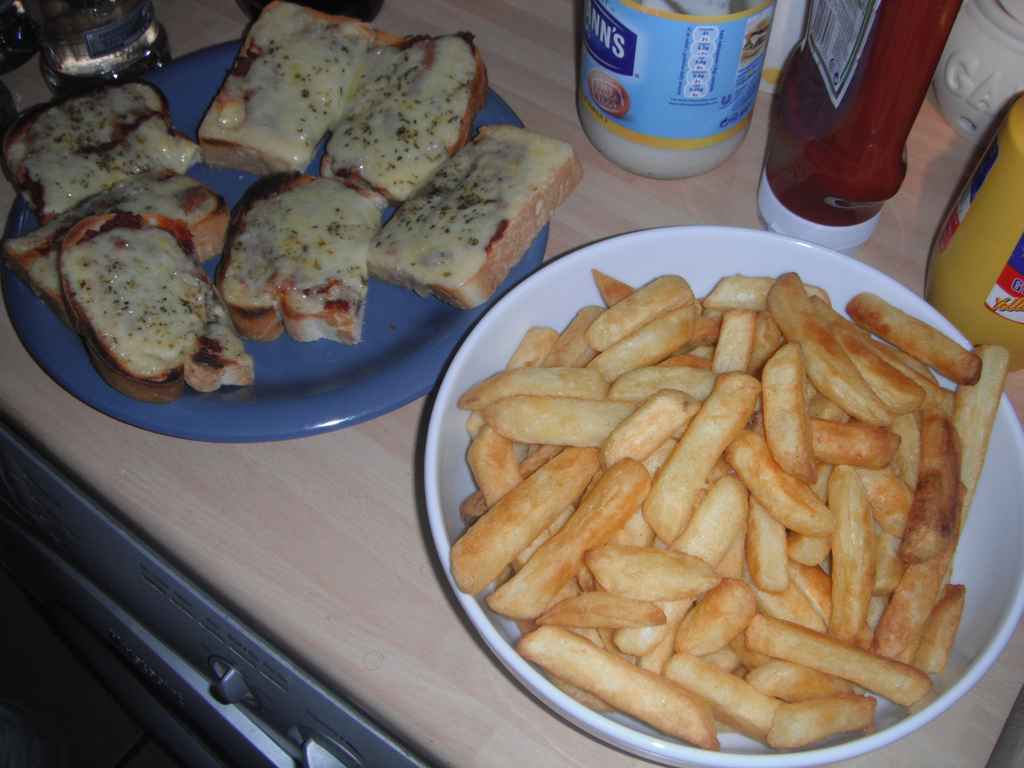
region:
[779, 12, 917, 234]
A bottle of ketchup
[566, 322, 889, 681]
A two to three servings of fries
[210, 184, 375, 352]
One piece of grilled cheese toast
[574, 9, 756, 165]
A large size of mayonnaise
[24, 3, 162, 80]
A glass of drink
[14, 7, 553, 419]
Seven pieces of grilled cheese toasts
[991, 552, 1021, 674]
A side of a large white bowl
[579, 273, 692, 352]
french fry on top of white plate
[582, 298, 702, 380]
french fry on top of white plate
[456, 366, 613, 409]
french fry on top of white plate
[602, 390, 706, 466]
french fry on top of white plate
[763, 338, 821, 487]
french fry on top of white plate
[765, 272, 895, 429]
french fry on top of white plate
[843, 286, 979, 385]
french fry on top of white plate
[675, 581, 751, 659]
french fry on top of white plate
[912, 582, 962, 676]
french fry on top of white plate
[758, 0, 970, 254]
The bottle of ketchup is upside down.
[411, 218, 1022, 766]
French fries in a white bowl.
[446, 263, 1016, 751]
The french fries are golden brown.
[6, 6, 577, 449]
The blue plate is full.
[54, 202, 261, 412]
The cheese on the bread is melted.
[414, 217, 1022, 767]
The white bowl is round.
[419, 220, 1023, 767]
The white bowl is full.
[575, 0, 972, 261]
A jar of mayonaisse is sitting beside the ketchup.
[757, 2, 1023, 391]
The ketchup is beside the bottle of mustard.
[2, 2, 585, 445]
Spices have been sprinkled on the cheesy pizza bread.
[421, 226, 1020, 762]
a serving of fries in a white bowl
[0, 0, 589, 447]
croque-monsieur on a blue plate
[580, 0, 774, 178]
a plastic jar of mayonnaise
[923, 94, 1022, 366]
a yellow container of mustard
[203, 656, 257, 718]
a silver dial on an oven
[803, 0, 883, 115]
a white and green sticker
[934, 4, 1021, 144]
a white porcelain jar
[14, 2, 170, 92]
a glass full of water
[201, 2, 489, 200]
melted cheese and herbs on bread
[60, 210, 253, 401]
a piece of garlic cheese bread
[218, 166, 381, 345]
a piece of garlic cheese bread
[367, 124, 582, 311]
a piece of garlic cheese bread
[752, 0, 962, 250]
a bottle of ketchup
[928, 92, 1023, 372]
a bottle of mustard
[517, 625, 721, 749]
a brown french fry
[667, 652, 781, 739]
a brown french fry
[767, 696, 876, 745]
a brown french fry